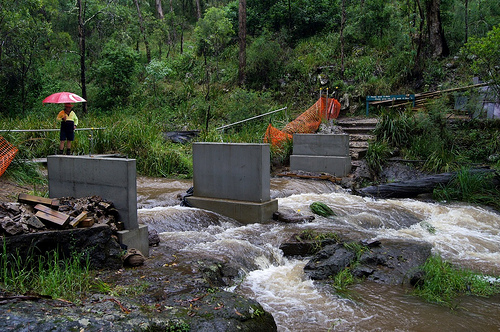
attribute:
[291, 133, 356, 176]
support — concrete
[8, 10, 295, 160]
vegetation — green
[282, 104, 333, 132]
fence — orange, mesh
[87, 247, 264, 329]
flat rock — large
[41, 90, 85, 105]
umbrella — red, white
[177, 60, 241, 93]
leaves — green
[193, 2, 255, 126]
trees — brown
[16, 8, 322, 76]
leaves — green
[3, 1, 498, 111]
trees — brown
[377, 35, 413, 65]
leave — green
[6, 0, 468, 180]
tree — brown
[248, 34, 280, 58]
leaves — green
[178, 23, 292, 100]
trees — brown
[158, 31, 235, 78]
leaves — green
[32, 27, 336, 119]
trees — brown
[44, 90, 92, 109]
umbrella — pink, open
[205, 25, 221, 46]
leaves — green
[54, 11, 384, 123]
trees — brown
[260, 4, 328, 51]
leaves — green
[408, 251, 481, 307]
grass — green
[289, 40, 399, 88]
leaves — green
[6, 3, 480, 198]
trees — brown